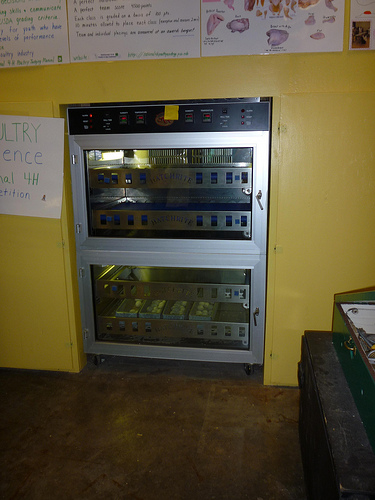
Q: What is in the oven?
A: Bread.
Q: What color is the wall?
A: Yellow.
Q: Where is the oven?
A: A kitchen.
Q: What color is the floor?
A: Brown.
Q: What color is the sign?
A: White.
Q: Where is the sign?
A: Next to the oven.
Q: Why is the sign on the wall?
A: To inform people.